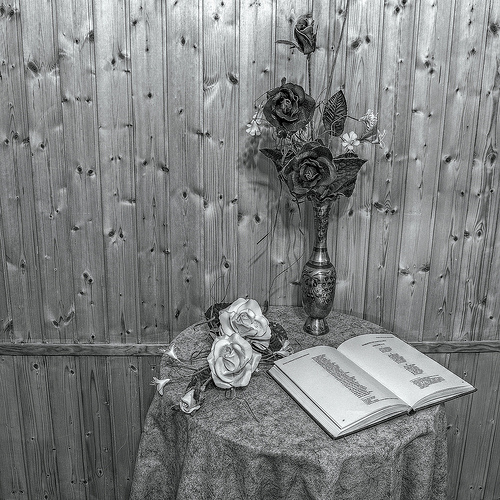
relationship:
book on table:
[266, 323, 482, 442] [119, 304, 451, 495]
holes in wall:
[75, 163, 85, 175] [2, 0, 499, 497]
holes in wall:
[85, 168, 95, 177] [2, 0, 499, 497]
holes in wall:
[36, 142, 45, 149] [2, 0, 499, 497]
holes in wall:
[143, 90, 153, 102] [2, 0, 499, 497]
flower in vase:
[260, 79, 317, 139] [294, 187, 342, 337]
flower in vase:
[278, 139, 335, 204] [294, 187, 342, 337]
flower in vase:
[287, 7, 320, 59] [294, 187, 342, 337]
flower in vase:
[338, 122, 364, 152] [294, 187, 342, 337]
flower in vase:
[238, 105, 266, 140] [294, 187, 342, 337]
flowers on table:
[198, 292, 277, 396] [119, 304, 451, 495]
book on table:
[266, 323, 482, 442] [158, 307, 447, 499]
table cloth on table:
[128, 306, 449, 497] [159, 304, 442, 459]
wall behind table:
[2, 0, 499, 497] [119, 304, 451, 495]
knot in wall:
[142, 236, 161, 268] [2, 0, 499, 497]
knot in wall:
[214, 248, 241, 281] [2, 0, 499, 497]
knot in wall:
[413, 254, 443, 281] [2, 0, 499, 497]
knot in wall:
[472, 288, 497, 315] [2, 0, 499, 497]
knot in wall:
[13, 254, 37, 279] [2, 0, 499, 497]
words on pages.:
[295, 330, 451, 408] [203, 297, 495, 459]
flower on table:
[294, 13, 319, 56] [119, 304, 451, 495]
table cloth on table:
[133, 299, 452, 499] [119, 304, 451, 495]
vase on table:
[297, 200, 348, 340] [119, 304, 451, 495]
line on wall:
[4, 341, 170, 356] [2, 0, 499, 497]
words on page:
[349, 374, 357, 386] [275, 344, 408, 431]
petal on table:
[170, 393, 199, 414] [119, 304, 451, 495]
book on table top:
[266, 323, 482, 442] [154, 302, 449, 469]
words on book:
[310, 348, 384, 407] [266, 332, 477, 442]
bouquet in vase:
[234, 7, 384, 204] [301, 204, 339, 334]